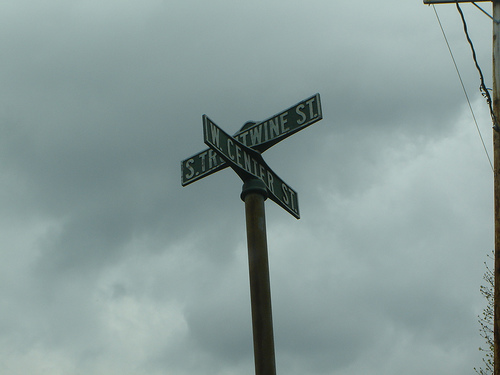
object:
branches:
[472, 218, 495, 373]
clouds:
[0, 0, 494, 375]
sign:
[181, 93, 324, 188]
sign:
[202, 113, 301, 220]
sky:
[0, 0, 494, 375]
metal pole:
[239, 120, 276, 375]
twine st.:
[185, 98, 318, 179]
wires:
[432, 2, 500, 172]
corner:
[469, 248, 497, 373]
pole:
[490, 1, 500, 373]